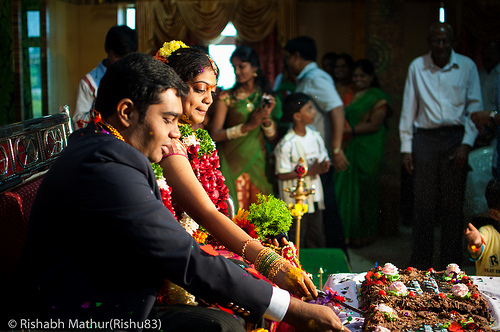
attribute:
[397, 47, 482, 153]
shirt — white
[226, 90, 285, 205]
dress — green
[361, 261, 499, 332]
cake — chocolate, cut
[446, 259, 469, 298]
flowers — pink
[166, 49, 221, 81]
hair — dark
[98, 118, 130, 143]
necklace — yellow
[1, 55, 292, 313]
man — sitting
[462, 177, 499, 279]
boy — pointing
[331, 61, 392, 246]
lady — smiling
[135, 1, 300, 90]
curtain — gold, red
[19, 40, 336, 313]
couple — cutting, newlywed, hindi, indian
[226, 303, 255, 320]
cuff links — gold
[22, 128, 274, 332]
suit — gray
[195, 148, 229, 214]
flowers — red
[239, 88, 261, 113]
necklace — gold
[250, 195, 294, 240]
bush — green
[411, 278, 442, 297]
writing — blue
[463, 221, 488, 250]
hand — small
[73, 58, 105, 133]
jacket — blue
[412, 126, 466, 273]
pants — gray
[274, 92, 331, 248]
child — looking